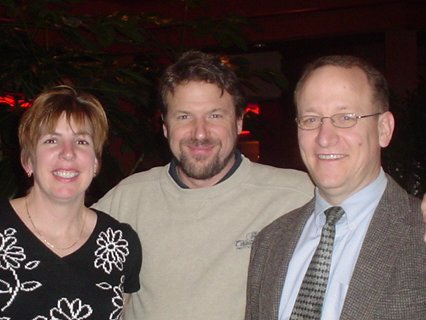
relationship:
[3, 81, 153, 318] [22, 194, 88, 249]
woman wearing necklace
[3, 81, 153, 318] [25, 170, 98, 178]
woman wearing earrings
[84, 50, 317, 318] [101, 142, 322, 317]
man wearing shirt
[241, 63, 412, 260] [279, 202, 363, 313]
man wears tie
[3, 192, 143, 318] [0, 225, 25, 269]
shirt has flowers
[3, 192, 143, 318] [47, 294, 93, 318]
shirt has flowers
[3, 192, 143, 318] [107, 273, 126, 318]
shirt has flowers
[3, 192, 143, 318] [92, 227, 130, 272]
shirt has flowers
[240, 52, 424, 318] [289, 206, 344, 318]
man wears tie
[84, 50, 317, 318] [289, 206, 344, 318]
man wears tie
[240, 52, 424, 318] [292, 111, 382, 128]
man wears glasses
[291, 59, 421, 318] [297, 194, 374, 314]
man wears dress shirt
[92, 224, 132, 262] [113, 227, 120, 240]
flower has petal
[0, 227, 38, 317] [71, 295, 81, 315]
flower has petal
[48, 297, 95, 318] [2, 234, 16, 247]
flower has petal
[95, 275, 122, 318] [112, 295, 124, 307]
flower has petal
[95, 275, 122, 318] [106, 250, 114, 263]
flower has petal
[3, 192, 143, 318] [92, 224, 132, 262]
shirt has flower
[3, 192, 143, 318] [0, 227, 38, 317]
shirt has flower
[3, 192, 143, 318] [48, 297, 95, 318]
shirt has flower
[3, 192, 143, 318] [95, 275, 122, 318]
shirt has flower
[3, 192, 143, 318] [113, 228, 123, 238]
shirt has petal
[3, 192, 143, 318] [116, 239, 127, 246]
shirt has petal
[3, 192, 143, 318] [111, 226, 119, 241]
shirt has petal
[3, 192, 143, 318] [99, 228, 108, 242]
shirt has petal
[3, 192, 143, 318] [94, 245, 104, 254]
shirt has petal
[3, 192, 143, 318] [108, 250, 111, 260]
shirt has petal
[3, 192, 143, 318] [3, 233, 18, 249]
shirt has petal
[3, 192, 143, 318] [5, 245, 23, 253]
shirt has petal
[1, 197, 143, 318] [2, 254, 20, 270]
flower shirt has flower petal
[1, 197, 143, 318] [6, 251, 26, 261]
flower shirt has flower petal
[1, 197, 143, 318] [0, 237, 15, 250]
flower shirt has flower petal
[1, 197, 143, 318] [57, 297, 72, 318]
flower shirt has flower petal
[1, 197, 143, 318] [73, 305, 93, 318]
flower shirt has flower petal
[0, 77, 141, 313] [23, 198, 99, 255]
lady wears necklace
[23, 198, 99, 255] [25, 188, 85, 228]
necklace on neck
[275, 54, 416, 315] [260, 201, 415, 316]
man wears gray jacket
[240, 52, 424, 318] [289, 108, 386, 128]
man wears eyeglasses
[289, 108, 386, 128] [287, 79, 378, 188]
eyeglasses on face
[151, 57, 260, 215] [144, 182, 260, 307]
man wears sweater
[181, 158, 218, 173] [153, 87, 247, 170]
hair on face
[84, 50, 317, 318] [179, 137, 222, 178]
man has beard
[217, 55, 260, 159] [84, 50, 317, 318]
glow behind man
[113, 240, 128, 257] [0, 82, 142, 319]
petal on shirt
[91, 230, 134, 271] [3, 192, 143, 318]
flower petal on shirt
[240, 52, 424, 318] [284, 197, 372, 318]
man wearing tie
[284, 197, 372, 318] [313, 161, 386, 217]
tie around neck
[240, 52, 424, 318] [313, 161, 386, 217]
man has neck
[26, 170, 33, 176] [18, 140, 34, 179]
earring in ear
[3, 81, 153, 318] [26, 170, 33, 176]
woman wearing earring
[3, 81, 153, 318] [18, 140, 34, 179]
woman has ear